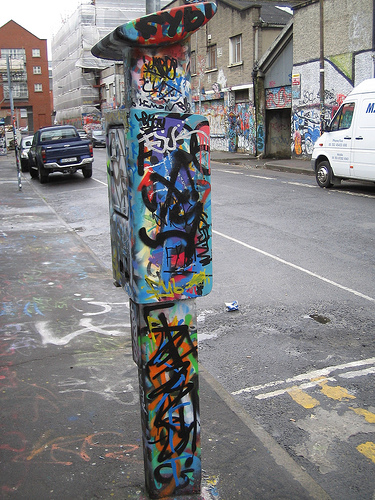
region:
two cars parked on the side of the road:
[10, 122, 101, 194]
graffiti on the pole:
[82, 7, 247, 498]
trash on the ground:
[220, 297, 240, 316]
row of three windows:
[30, 45, 48, 103]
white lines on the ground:
[227, 354, 374, 412]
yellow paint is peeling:
[329, 390, 366, 414]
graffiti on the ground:
[2, 208, 230, 497]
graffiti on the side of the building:
[293, 52, 374, 151]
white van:
[297, 83, 374, 192]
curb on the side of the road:
[260, 161, 316, 178]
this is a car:
[322, 87, 371, 192]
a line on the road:
[280, 248, 336, 313]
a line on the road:
[238, 219, 300, 288]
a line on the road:
[214, 224, 276, 284]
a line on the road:
[216, 161, 295, 199]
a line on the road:
[251, 240, 305, 289]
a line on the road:
[236, 369, 314, 419]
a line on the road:
[327, 344, 364, 397]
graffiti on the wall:
[214, 76, 313, 163]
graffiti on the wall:
[220, 90, 307, 154]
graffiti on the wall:
[216, 63, 323, 161]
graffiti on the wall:
[222, 88, 322, 168]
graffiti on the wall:
[211, 78, 318, 168]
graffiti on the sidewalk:
[10, 226, 113, 459]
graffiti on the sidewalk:
[10, 241, 117, 465]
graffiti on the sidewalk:
[5, 242, 121, 445]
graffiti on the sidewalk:
[4, 237, 104, 413]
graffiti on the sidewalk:
[0, 230, 141, 470]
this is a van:
[312, 83, 374, 154]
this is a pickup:
[30, 125, 103, 183]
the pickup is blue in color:
[56, 144, 71, 157]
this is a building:
[4, 20, 70, 121]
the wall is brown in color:
[7, 29, 30, 40]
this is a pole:
[5, 55, 20, 116]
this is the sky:
[27, 11, 48, 24]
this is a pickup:
[31, 120, 87, 170]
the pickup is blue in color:
[65, 143, 83, 158]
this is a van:
[333, 100, 369, 145]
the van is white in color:
[360, 144, 372, 162]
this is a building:
[6, 19, 56, 115]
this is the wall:
[4, 27, 32, 48]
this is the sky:
[27, 4, 54, 27]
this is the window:
[31, 48, 42, 57]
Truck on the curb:
[22, 123, 104, 181]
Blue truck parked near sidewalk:
[20, 122, 105, 188]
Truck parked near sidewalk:
[18, 119, 111, 188]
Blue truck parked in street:
[16, 122, 108, 180]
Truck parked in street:
[19, 122, 107, 190]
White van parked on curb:
[297, 76, 373, 189]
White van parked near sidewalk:
[304, 81, 372, 193]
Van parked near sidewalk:
[289, 64, 374, 195]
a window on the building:
[29, 50, 45, 60]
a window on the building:
[222, 30, 246, 58]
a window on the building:
[211, 43, 223, 65]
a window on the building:
[189, 49, 190, 66]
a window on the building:
[30, 46, 39, 50]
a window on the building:
[35, 64, 42, 77]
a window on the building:
[34, 80, 50, 95]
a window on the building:
[19, 76, 40, 107]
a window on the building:
[0, 86, 17, 105]